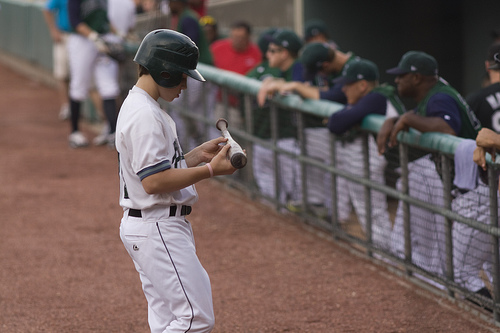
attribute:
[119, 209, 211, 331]
pants — white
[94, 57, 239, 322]
player — baseball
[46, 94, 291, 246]
uniform — white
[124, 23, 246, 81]
helmet — dark blue, batting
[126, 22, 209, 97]
helmet — dark blue, protective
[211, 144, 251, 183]
hand — white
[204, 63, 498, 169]
barrier top — green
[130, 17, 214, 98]
helmet — green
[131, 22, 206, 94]
helmet — green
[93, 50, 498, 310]
barrier — metal 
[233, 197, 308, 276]
ground — Dirt 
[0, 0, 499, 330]
metal fence — green , metal 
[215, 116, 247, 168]
bat — wooden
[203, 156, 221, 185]
band — wrist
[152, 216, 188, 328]
trousers — white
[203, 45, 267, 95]
shirt — red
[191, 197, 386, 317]
dirt — red